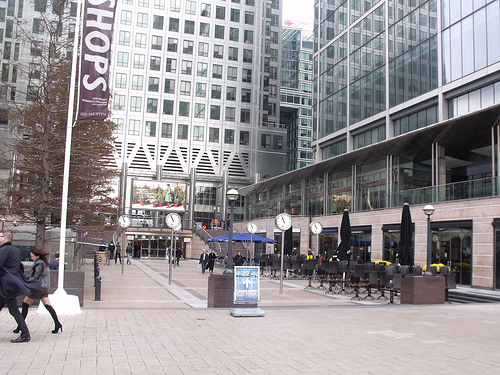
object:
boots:
[13, 302, 62, 334]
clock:
[275, 213, 292, 231]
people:
[49, 250, 66, 270]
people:
[199, 249, 215, 274]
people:
[99, 241, 133, 265]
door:
[158, 239, 166, 257]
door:
[150, 240, 158, 257]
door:
[141, 240, 148, 257]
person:
[115, 242, 122, 264]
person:
[199, 249, 209, 274]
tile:
[0, 259, 500, 375]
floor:
[0, 259, 500, 375]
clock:
[165, 213, 181, 228]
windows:
[128, 0, 250, 146]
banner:
[75, 0, 117, 121]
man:
[0, 234, 30, 343]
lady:
[13, 250, 62, 334]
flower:
[423, 263, 451, 272]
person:
[233, 252, 244, 266]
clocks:
[309, 221, 323, 234]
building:
[0, 0, 500, 291]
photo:
[0, 0, 500, 375]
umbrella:
[399, 202, 413, 265]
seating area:
[260, 254, 455, 304]